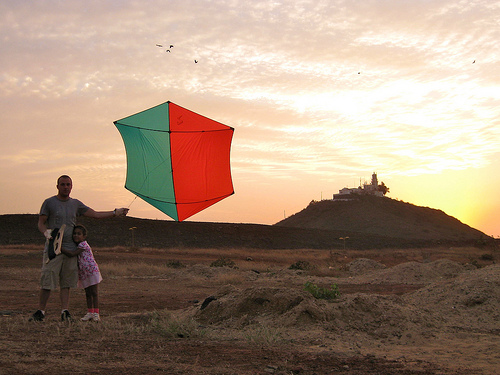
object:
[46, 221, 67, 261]
spool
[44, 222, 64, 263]
string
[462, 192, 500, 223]
sun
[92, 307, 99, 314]
sock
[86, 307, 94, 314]
sock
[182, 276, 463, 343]
weeds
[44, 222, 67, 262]
hold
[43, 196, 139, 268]
string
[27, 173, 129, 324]
guy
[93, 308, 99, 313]
sock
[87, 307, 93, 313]
sock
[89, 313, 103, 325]
shoe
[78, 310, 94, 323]
shoe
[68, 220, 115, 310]
girl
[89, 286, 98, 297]
knee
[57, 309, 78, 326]
shoes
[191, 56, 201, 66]
birds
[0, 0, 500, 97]
sky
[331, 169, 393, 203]
house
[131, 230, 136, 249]
pole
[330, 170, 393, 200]
building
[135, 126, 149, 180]
string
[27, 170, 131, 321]
man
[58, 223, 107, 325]
girl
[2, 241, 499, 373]
ground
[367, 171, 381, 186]
lighthouse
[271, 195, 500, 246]
hill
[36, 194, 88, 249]
shirt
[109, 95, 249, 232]
kite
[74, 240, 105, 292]
outfit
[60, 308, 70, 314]
socks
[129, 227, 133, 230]
lights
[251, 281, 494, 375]
dirt